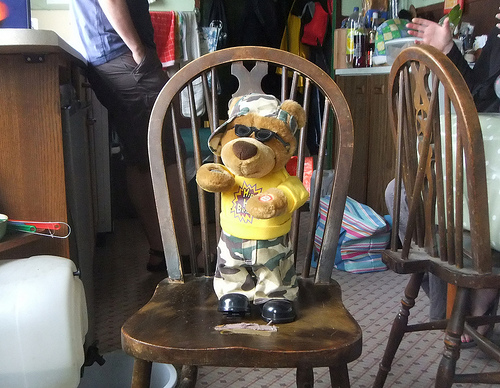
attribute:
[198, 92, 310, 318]
teddybear — standing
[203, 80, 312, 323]
teddy bear — standing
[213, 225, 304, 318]
pants — camoflauge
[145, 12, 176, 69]
towel — red, hanging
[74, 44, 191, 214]
shorts — black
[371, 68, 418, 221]
cabinet — wooden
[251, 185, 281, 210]
red button — white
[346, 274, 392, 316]
carpeting — gray 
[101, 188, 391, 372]
seat — wooden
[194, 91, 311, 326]
bear — standing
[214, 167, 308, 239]
shirt — yellow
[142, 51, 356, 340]
chair — wooden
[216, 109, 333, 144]
toy sunglasses — plastic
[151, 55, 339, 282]
chair back — wooden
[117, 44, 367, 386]
chair — wood, brown, wooden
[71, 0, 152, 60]
shirt — blue